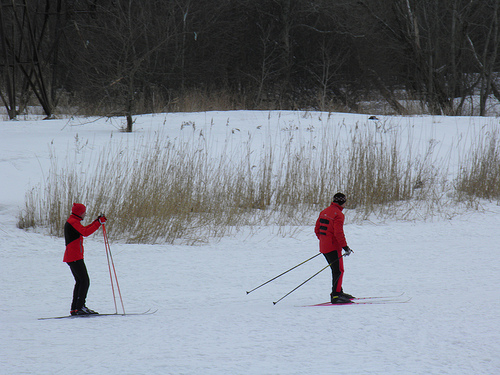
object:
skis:
[33, 308, 151, 321]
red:
[60, 202, 109, 263]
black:
[78, 267, 83, 301]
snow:
[207, 305, 486, 374]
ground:
[166, 244, 259, 278]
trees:
[29, 4, 59, 120]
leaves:
[254, 21, 274, 36]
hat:
[68, 199, 87, 220]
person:
[59, 200, 108, 318]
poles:
[93, 211, 119, 315]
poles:
[271, 249, 353, 307]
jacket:
[309, 205, 357, 257]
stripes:
[315, 217, 334, 238]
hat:
[329, 190, 351, 207]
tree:
[97, 14, 157, 117]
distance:
[19, 23, 425, 126]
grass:
[103, 129, 399, 234]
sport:
[25, 219, 158, 324]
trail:
[20, 294, 499, 317]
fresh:
[442, 315, 492, 374]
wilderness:
[12, 59, 491, 229]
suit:
[55, 202, 92, 312]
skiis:
[274, 296, 421, 306]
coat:
[57, 216, 108, 267]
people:
[310, 187, 360, 308]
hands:
[95, 214, 112, 225]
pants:
[64, 259, 98, 314]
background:
[12, 10, 475, 175]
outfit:
[310, 197, 348, 303]